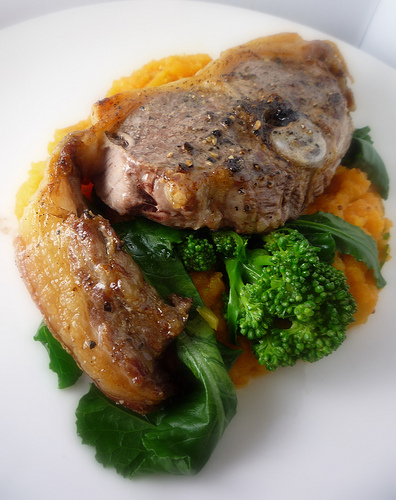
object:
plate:
[2, 3, 394, 499]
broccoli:
[230, 230, 358, 364]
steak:
[96, 30, 363, 248]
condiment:
[121, 61, 336, 172]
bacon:
[8, 133, 186, 418]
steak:
[17, 162, 193, 424]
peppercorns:
[178, 154, 194, 172]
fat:
[272, 34, 355, 59]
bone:
[263, 114, 327, 167]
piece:
[220, 221, 361, 377]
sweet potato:
[100, 45, 213, 86]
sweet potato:
[298, 166, 395, 364]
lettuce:
[73, 325, 245, 481]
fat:
[12, 91, 191, 422]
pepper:
[64, 203, 193, 375]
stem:
[219, 232, 270, 287]